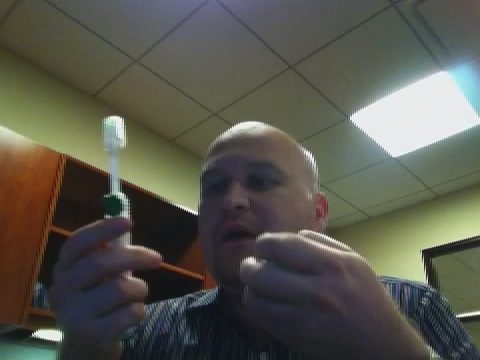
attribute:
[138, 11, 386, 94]
ceiling — white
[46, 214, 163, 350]
hand — man's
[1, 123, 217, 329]
cabinet — wooden, brown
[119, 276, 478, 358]
shirt — gray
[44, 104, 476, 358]
man — blue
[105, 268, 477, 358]
shirt — striped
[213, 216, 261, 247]
mouth — open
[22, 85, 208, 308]
cabinet — brown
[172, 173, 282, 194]
eyes — brown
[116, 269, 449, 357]
shirt — striped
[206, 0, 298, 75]
trim — black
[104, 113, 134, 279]
toothbrush — white